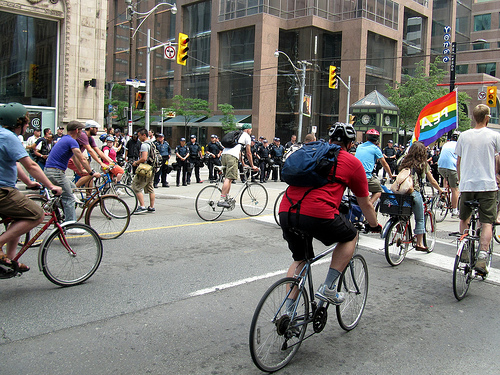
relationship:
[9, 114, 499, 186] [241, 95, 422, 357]
people riding bikes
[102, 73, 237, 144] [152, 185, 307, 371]
trees beside road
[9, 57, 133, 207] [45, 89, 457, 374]
building beside road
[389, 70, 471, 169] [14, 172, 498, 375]
tree beside road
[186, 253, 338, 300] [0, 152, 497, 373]
paint on ground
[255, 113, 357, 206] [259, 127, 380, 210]
pack on man's back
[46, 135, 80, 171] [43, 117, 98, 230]
shirt on man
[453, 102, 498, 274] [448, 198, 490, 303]
man on bicycle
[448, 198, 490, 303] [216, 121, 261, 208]
bicycle on man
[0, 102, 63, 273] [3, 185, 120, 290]
person sitting on bike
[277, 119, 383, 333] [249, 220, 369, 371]
person sitting on bike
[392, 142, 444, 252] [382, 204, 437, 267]
person sitting on bike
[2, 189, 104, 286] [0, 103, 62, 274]
bike sitting on people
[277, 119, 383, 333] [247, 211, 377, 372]
person sitting on bike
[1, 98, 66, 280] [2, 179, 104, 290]
person sitting on bike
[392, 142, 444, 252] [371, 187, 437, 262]
person sitting on bike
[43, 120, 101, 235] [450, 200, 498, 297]
man sitting on bike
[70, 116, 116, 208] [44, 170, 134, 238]
person sitting on bike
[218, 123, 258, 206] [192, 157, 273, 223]
man sitting on bike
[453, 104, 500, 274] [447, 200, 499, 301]
man sitting on bike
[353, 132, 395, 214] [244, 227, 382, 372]
person sitting on bike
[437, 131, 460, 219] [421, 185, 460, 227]
bike rider sitting on bike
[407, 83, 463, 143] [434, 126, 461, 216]
flag held by bike rider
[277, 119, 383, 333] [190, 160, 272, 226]
person sitting bike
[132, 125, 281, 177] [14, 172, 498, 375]
police standing beside road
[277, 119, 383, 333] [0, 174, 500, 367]
person going down street